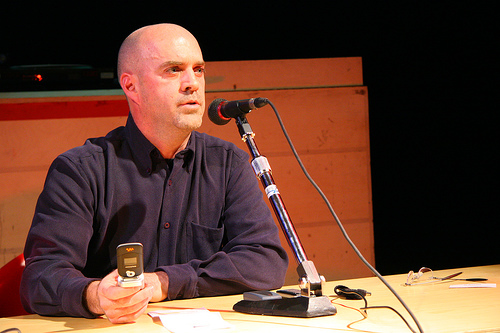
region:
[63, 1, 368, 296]
Man with a mic.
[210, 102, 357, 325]
Mic on the table.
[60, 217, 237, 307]
Cell phone in the man's hand.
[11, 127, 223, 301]
Purple shirt worn by the man.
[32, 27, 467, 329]
Man sitting at a table.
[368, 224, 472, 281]
Glasses on the table.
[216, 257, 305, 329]
Base of the microphone/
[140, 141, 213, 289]
Buttons on the shirt.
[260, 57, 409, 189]
Wood bench behind the table.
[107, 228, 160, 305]
Flip phone with black color.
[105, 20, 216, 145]
a man without hair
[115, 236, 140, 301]
a black and silver cell phone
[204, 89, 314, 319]
a microphone on a stand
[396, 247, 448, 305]
a pair of glasses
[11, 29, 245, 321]
a man holding a cell phone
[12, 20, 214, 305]
a man wearing a long sleeved shirt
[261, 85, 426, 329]
a black microphone wire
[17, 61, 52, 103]
a black box with a red light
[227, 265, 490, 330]
a wooden table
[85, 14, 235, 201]
a man speaking into a microphone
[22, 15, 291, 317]
bald man holding cell phone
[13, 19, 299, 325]
bald man wearing purple shirt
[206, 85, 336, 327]
black and red microphone in front of man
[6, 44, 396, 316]
brown wooden partition behind man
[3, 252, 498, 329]
light oak table under man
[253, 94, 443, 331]
black cord connected to microphone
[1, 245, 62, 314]
red chair under man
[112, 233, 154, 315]
silver open flip phone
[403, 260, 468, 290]
clear reading glasses on trable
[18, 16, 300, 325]
man wearing button down shirt talking into microphone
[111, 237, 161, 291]
a flip cell phone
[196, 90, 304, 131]
a microphone in a stand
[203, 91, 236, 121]
red band on microphone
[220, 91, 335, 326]
a black, metal stand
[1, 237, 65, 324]
a hard red chair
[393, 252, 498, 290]
a pair of reading glasses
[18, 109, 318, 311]
a dark, button up shirt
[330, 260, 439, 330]
a black electrical cord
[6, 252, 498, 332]
a light wooden desk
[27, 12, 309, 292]
a bald man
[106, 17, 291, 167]
bald man speaking into microphone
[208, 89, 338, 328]
black microphone sitting on table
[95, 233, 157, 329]
man holding a flip phone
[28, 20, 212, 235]
man wearing a dark grey shirt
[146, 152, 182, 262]
dark grey button front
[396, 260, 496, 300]
reading glasses on a table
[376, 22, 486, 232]
completely dark back stage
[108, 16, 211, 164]
man with shaved head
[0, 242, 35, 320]
partial back of a red chair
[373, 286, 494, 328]
wood conference table